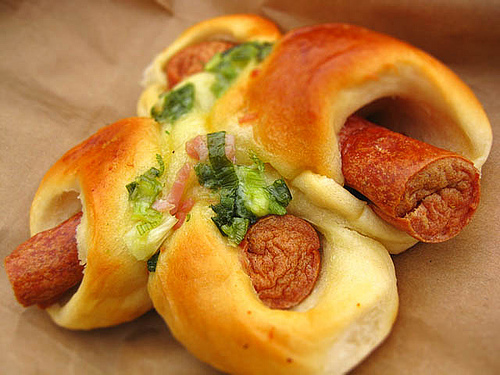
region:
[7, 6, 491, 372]
a bread with hot dogs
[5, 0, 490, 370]
a bread with holes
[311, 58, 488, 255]
a hole in a bread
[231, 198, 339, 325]
a hole in a bread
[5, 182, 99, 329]
a hole in a bread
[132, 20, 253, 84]
a hole in a bread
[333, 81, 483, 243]
a hot dog in a hole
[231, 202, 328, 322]
a hot dog in a hole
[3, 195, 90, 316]
a hot dog in a hole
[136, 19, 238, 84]
a hot dog in a hole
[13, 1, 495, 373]
hotdog slices in buns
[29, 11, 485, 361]
buns around hotdog slices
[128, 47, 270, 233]
green garnish on hotdogs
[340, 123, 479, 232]
hotdog chunk hanging out of bun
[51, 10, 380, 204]
golden brown tops of buns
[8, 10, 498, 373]
countertop hotdogs are sitting on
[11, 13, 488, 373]
four hotdog in four buns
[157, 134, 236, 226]
pink garnish on buns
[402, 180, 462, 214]
slice in the end of the hotdog chunk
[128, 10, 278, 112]
hotdog in bun in background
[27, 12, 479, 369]
a unique piece of food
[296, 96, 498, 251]
a hotdog sticking out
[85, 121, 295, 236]
green slices of vegetable on top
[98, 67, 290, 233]
melted cheese on top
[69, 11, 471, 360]
four sections with hot dogs sticking out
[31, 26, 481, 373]
bread encasing hot dogs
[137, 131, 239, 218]
small pieces of tomatoe on top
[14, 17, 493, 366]
a new kitchen creation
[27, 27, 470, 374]
dough around hot dogs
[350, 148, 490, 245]
one hot dog is starting to split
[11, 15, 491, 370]
a dinner with pepperonis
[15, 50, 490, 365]
food with meat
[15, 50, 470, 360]
a meal with garnishments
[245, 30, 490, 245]
bread surrounds a meat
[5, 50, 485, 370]
fancy dishes with bread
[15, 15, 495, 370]
fancy dishes with pepperoni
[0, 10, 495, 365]
an appetizer with sausage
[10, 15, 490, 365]
an appetizer with bread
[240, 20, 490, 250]
toasted bread with meat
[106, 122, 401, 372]
green garnishments on bread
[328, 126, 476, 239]
The hot dog on the right.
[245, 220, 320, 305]
The hot dog in the middle.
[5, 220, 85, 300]
The hot dog on the left.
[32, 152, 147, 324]
The croissant on the left.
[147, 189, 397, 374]
The croissant in the middle.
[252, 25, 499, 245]
The croissant on the right.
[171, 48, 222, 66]
The hot dog in the back.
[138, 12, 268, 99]
The croissant in the back.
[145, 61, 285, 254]
The lettuce on the dish.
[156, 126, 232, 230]
The pieces of ham/bacon on the dish.